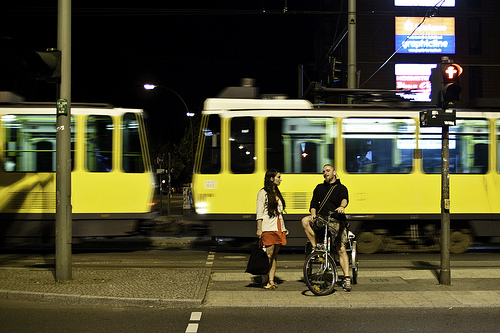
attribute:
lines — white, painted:
[164, 302, 222, 331]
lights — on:
[281, 118, 492, 134]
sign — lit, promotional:
[395, 16, 455, 53]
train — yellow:
[6, 77, 493, 255]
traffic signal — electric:
[433, 55, 467, 117]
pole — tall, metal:
[51, 3, 75, 283]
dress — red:
[259, 193, 286, 245]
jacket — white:
[255, 185, 287, 232]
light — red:
[439, 59, 464, 110]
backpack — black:
[244, 244, 270, 276]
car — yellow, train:
[169, 85, 494, 272]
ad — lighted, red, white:
[395, 62, 443, 103]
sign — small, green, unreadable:
[57, 97, 69, 119]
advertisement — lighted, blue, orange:
[383, 13, 463, 36]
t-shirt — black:
[305, 177, 348, 218]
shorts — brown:
[310, 211, 348, 248]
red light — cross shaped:
[442, 60, 470, 83]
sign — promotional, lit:
[384, 54, 449, 115]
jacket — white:
[254, 188, 291, 233]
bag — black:
[246, 248, 270, 277]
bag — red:
[239, 241, 275, 281]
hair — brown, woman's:
[263, 167, 285, 216]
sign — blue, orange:
[394, 19, 457, 59]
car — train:
[135, 103, 477, 258]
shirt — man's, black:
[310, 179, 352, 224]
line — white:
[184, 321, 198, 331]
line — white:
[186, 308, 202, 322]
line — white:
[203, 260, 213, 265]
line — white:
[205, 252, 215, 259]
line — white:
[209, 250, 216, 255]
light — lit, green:
[327, 53, 344, 87]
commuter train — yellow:
[2, 94, 483, 254]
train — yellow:
[1, 95, 484, 255]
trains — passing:
[2, 90, 499, 273]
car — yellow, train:
[0, 91, 160, 261]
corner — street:
[8, 69, 498, 331]